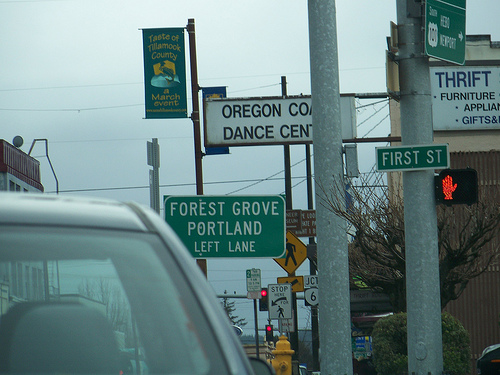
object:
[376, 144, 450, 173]
sign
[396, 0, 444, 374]
pole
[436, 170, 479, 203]
sign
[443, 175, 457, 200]
hand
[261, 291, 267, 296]
light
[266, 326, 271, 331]
light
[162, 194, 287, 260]
sign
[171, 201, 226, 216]
words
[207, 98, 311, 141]
sign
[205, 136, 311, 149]
pole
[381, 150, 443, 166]
first st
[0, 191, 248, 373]
car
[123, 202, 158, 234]
slit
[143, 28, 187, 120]
flag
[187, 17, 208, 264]
pole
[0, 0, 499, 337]
sky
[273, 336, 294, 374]
pump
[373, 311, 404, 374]
plant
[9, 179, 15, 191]
window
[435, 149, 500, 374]
wall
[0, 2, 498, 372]
picture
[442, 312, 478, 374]
bush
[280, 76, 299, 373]
pole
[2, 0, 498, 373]
area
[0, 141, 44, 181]
top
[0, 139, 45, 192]
building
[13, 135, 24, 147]
dish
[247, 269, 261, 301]
sign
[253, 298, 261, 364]
pole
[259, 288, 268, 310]
signal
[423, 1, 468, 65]
sign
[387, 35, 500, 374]
place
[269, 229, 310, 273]
sign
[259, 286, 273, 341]
lights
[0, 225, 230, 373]
window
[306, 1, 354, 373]
pole